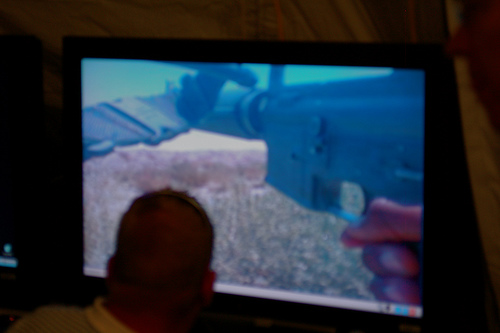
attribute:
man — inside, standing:
[4, 186, 216, 331]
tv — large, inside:
[60, 34, 445, 332]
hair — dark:
[116, 189, 212, 318]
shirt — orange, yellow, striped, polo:
[4, 295, 133, 332]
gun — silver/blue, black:
[237, 70, 423, 222]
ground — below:
[86, 148, 375, 301]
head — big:
[106, 193, 216, 332]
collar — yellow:
[86, 297, 133, 332]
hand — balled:
[342, 197, 421, 303]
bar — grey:
[84, 266, 423, 316]